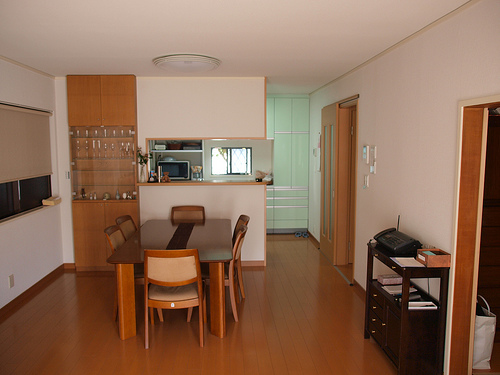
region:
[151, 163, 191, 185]
small shelf-size microwave oven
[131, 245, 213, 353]
wooden dining table chair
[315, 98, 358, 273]
wood door with glass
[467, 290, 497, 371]
paper shopping bag with handle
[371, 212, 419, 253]
answering machine with cordless phone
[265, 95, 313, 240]
clear glass window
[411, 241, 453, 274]
wooden box with label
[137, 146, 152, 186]
ceramic vase with flower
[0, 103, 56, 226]
beige window shade with cord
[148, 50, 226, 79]
round ceiling light fixture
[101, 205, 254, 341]
the dining table in the kitchen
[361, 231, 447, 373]
a small table by the wall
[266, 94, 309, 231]
the green wall at the end of the hallway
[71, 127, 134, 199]
shelves holding assorted wine glasses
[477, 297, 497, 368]
a white bag sitting on the floor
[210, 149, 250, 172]
a small window in the wall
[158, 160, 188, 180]
a microwabe in the kitchen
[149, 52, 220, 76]
a light in the ceiling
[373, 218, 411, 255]
a phone on the shelf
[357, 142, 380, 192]
assorted switches in the wall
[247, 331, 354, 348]
shiny brown floor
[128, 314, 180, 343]
leg of brown chair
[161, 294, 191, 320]
white spot on chair seat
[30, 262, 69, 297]
brown edge of white wall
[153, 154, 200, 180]
black microwave on counter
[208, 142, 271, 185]
opening on the wall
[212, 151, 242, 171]
tree limbs in the distance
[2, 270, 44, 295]
electrical outlet on the wall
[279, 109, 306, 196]
green tiles on the wall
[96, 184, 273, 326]
large brown dining room table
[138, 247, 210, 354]
wooden chair at head of table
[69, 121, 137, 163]
formal drinkware above bar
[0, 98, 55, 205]
pull down shade on window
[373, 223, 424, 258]
fax machine on table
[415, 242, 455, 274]
inbox on table against wall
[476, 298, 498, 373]
white bag of misc items in other room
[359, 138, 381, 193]
series of frames on wall opposite window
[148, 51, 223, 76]
flat circular light dome above dining table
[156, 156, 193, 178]
microwave in kitchen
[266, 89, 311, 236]
foam green cabinets in kitchen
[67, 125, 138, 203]
display shelf holding wine glasses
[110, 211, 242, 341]
Wooden dining room table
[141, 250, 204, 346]
one brown & tan chair in a matching set of six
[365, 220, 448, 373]
small shelf/cabinet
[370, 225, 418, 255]
fax machine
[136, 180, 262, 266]
kitchen bar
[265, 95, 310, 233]
floor to ceiling kitchen cabnets painted white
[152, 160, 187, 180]
black microwave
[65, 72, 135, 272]
floor-to-ceiling dining room cabinets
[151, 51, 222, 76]
dining room light